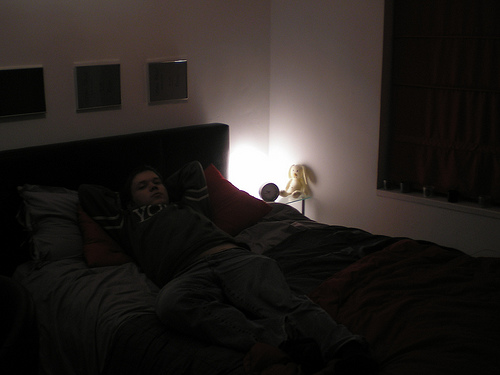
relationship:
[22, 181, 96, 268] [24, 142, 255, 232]
pillow at head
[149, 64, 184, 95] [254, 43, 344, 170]
frame on wall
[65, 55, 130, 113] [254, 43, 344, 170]
frame on wall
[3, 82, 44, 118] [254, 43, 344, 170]
frame on wall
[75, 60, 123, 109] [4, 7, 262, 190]
frame on wall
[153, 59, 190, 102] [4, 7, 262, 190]
frame on wall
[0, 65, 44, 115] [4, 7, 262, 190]
frame on wall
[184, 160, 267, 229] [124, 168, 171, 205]
pillow under head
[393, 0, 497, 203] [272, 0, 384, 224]
window on wall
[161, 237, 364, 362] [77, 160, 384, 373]
sweatpants on boy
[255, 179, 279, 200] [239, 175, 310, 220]
clock on nightstand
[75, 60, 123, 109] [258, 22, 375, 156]
frame in wall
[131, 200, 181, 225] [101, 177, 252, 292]
white letters on front of shirt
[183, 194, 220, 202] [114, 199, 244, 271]
stripe on shirt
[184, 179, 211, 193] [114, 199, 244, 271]
stripe on shirt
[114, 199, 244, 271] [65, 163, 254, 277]
shirt of man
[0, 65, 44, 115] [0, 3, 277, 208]
frame on wall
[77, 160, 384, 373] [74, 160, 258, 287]
boy wearing shirt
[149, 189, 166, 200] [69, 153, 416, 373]
mouth of man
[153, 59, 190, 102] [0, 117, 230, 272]
frame above headboard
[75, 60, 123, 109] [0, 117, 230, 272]
frame above headboard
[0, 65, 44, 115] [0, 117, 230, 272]
frame above headboard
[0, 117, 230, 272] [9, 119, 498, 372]
headboard of bed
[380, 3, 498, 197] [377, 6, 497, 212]
curtain on window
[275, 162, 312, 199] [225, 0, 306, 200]
stuffed rabbit in corner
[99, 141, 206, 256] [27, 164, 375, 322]
boy laying on bed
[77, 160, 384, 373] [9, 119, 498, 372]
boy sleeping on bed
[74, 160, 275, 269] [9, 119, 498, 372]
pillow on bed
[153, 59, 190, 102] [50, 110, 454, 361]
frame hanging above bed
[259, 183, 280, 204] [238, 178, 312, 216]
clock on nightstand